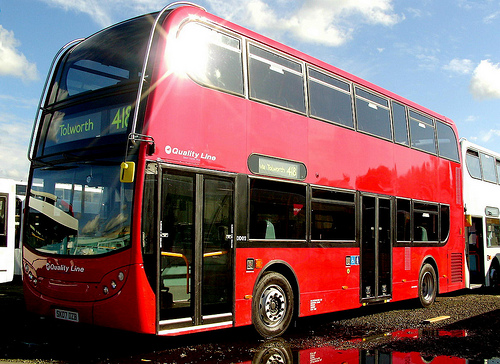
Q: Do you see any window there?
A: Yes, there is a window.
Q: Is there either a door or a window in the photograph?
A: Yes, there is a window.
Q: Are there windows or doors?
A: Yes, there is a window.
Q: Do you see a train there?
A: No, there are no trains.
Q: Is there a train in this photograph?
A: No, there are no trains.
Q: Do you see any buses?
A: Yes, there is a bus.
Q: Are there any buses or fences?
A: Yes, there is a bus.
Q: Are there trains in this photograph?
A: No, there are no trains.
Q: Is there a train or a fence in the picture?
A: No, there are no trains or fences.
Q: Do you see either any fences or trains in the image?
A: No, there are no trains or fences.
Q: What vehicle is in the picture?
A: The vehicle is a bus.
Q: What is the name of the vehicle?
A: The vehicle is a bus.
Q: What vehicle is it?
A: The vehicle is a bus.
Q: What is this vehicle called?
A: This is a bus.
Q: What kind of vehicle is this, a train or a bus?
A: This is a bus.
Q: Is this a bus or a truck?
A: This is a bus.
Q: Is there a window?
A: Yes, there is a window.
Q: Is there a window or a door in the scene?
A: Yes, there is a window.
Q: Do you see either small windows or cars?
A: Yes, there is a small window.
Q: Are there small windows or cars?
A: Yes, there is a small window.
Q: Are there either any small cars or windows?
A: Yes, there is a small window.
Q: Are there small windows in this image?
A: Yes, there is a small window.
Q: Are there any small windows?
A: Yes, there is a small window.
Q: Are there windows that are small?
A: Yes, there is a window that is small.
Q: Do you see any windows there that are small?
A: Yes, there is a window that is small.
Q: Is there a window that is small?
A: Yes, there is a window that is small.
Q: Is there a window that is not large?
A: Yes, there is a small window.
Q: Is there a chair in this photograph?
A: No, there are no chairs.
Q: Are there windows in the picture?
A: Yes, there is a window.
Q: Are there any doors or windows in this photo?
A: Yes, there is a window.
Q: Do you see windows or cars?
A: Yes, there is a window.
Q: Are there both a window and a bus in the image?
A: Yes, there are both a window and a bus.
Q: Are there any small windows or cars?
A: Yes, there is a small window.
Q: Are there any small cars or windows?
A: Yes, there is a small window.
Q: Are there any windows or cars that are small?
A: Yes, the window is small.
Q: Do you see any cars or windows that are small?
A: Yes, the window is small.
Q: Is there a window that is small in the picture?
A: Yes, there is a small window.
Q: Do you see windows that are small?
A: Yes, there is a window that is small.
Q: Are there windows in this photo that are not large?
A: Yes, there is a small window.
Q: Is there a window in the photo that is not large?
A: Yes, there is a small window.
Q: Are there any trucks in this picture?
A: No, there are no trucks.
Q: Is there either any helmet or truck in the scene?
A: No, there are no trucks or helmets.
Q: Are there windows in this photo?
A: Yes, there is a window.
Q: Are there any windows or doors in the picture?
A: Yes, there is a window.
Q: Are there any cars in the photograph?
A: No, there are no cars.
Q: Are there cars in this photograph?
A: No, there are no cars.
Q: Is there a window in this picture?
A: Yes, there is a window.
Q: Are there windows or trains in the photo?
A: Yes, there is a window.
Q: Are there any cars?
A: No, there are no cars.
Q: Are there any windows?
A: Yes, there is a window.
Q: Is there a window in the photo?
A: Yes, there is a window.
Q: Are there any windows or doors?
A: Yes, there is a window.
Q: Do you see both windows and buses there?
A: Yes, there are both a window and a bus.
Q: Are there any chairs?
A: No, there are no chairs.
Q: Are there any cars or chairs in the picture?
A: No, there are no chairs or cars.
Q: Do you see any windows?
A: Yes, there is a window.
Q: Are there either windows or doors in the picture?
A: Yes, there is a window.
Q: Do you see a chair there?
A: No, there are no chairs.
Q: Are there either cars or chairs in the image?
A: No, there are no chairs or cars.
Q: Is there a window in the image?
A: Yes, there is a window.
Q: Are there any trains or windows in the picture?
A: Yes, there is a window.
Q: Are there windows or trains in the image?
A: Yes, there is a window.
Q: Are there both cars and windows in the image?
A: No, there is a window but no cars.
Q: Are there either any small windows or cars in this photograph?
A: Yes, there is a small window.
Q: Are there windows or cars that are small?
A: Yes, the window is small.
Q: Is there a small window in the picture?
A: Yes, there is a small window.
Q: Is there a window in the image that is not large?
A: Yes, there is a small window.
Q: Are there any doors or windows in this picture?
A: Yes, there is a window.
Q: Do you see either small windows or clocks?
A: Yes, there is a small window.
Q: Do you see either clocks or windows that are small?
A: Yes, the window is small.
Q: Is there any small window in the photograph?
A: Yes, there is a small window.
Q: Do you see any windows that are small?
A: Yes, there is a window that is small.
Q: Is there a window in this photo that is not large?
A: Yes, there is a small window.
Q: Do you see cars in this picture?
A: No, there are no cars.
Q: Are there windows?
A: Yes, there is a window.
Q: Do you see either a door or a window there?
A: Yes, there is a window.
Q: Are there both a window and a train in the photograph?
A: No, there is a window but no trains.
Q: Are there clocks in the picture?
A: No, there are no clocks.